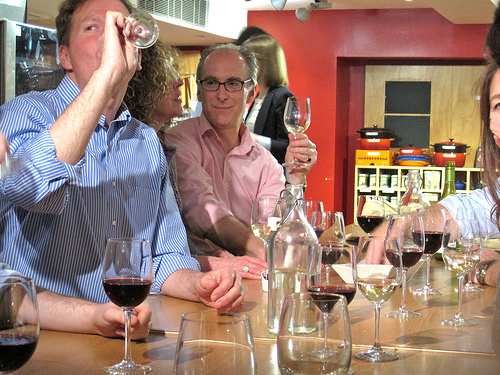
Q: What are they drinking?
A: Wine.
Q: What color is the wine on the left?
A: Red.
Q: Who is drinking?
A: The man in striped shirt.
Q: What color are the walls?
A: Red.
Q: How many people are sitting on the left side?
A: Three.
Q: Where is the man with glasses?
A: Sitting next to the woman.